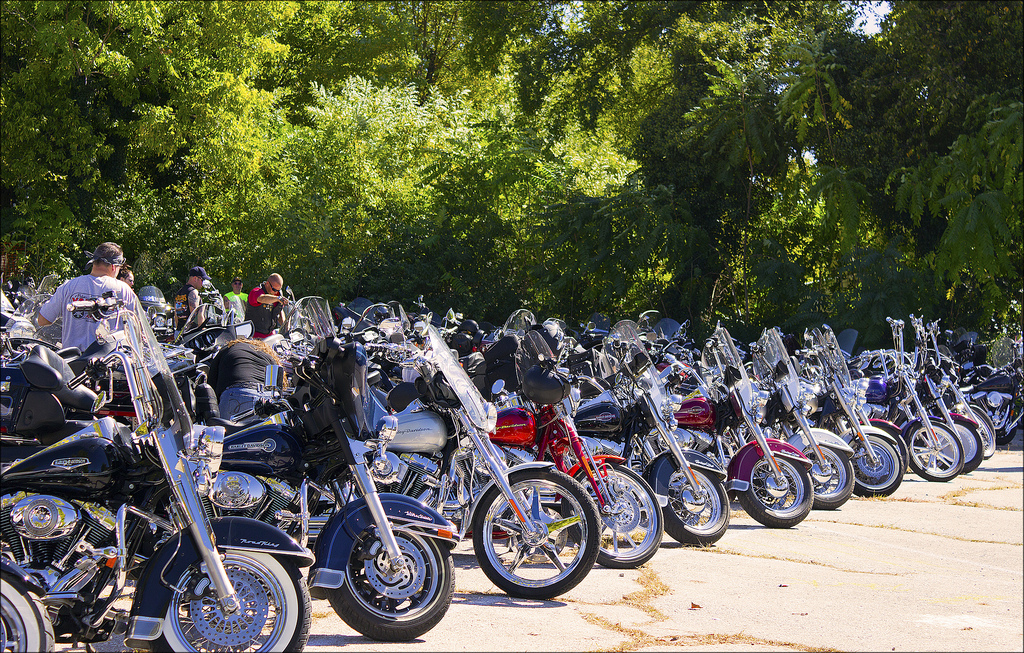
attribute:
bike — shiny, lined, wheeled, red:
[232, 324, 412, 612]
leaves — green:
[141, 20, 261, 78]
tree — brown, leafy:
[627, 237, 710, 309]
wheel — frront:
[434, 433, 585, 578]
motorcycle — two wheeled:
[392, 311, 582, 532]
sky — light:
[856, 8, 881, 25]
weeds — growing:
[969, 340, 991, 364]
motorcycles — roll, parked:
[249, 315, 518, 472]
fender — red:
[545, 413, 602, 468]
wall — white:
[491, 544, 508, 572]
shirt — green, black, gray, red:
[63, 283, 101, 308]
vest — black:
[247, 305, 279, 335]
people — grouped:
[11, 241, 287, 327]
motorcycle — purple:
[680, 312, 815, 526]